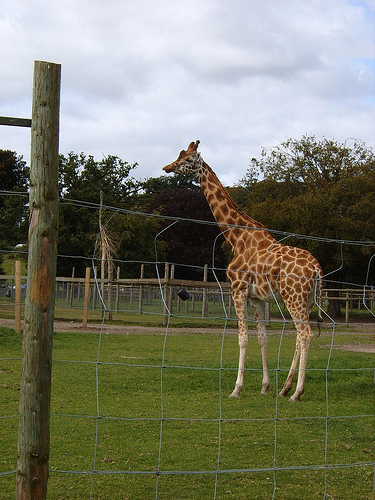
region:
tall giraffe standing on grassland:
[150, 137, 343, 404]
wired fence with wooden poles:
[11, 126, 366, 496]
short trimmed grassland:
[61, 336, 366, 479]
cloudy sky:
[6, 27, 370, 183]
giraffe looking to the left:
[156, 138, 342, 400]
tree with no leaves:
[91, 194, 118, 317]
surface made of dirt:
[4, 315, 362, 340]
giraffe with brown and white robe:
[161, 141, 331, 407]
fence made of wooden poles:
[6, 265, 370, 328]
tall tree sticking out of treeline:
[234, 128, 363, 213]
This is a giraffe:
[147, 133, 330, 405]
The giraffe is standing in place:
[163, 137, 342, 411]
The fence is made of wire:
[66, 286, 359, 496]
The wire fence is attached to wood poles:
[22, 155, 64, 496]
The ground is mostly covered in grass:
[61, 331, 359, 486]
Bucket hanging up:
[169, 278, 194, 305]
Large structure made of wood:
[64, 260, 368, 313]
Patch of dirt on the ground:
[11, 303, 232, 333]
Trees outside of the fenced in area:
[57, 160, 351, 247]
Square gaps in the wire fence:
[96, 363, 160, 417]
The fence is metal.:
[1, 186, 372, 497]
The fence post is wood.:
[16, 54, 66, 497]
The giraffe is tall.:
[152, 132, 332, 412]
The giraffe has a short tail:
[161, 136, 357, 406]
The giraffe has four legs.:
[155, 133, 340, 412]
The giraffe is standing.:
[155, 137, 338, 413]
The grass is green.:
[1, 330, 373, 498]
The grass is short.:
[0, 326, 373, 497]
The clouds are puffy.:
[0, 1, 372, 127]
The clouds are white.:
[1, 0, 373, 159]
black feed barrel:
[176, 284, 191, 300]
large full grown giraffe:
[160, 138, 324, 402]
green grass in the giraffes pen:
[0, 325, 373, 499]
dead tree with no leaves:
[92, 187, 118, 307]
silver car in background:
[2, 279, 27, 300]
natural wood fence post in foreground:
[15, 56, 63, 498]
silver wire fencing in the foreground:
[1, 186, 374, 498]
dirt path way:
[1, 312, 373, 337]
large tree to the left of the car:
[0, 147, 32, 293]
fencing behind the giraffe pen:
[0, 260, 374, 325]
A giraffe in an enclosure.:
[15, 61, 353, 487]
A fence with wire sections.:
[64, 204, 367, 493]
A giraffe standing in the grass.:
[155, 130, 337, 410]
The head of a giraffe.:
[154, 129, 203, 181]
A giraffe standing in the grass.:
[183, 135, 207, 185]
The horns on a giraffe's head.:
[164, 125, 207, 184]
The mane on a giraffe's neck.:
[197, 153, 277, 243]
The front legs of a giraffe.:
[225, 248, 272, 398]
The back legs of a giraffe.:
[268, 273, 317, 411]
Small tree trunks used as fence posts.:
[7, 53, 219, 482]